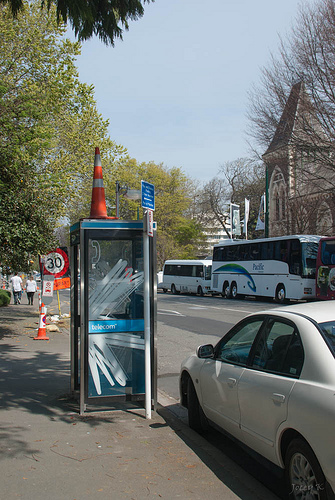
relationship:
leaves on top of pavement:
[8, 314, 30, 339] [5, 300, 69, 416]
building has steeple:
[243, 87, 334, 245] [277, 76, 335, 156]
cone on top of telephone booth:
[85, 142, 113, 235] [65, 226, 164, 404]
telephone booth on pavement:
[65, 226, 164, 404] [0, 300, 274, 500]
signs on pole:
[38, 247, 73, 295] [54, 292, 74, 330]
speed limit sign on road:
[42, 249, 58, 274] [55, 287, 193, 392]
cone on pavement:
[31, 301, 54, 344] [0, 300, 274, 500]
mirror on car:
[192, 339, 217, 366] [197, 320, 326, 446]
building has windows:
[243, 87, 334, 245] [259, 169, 292, 229]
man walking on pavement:
[9, 269, 22, 309] [0, 300, 274, 500]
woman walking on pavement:
[21, 266, 36, 306] [0, 300, 274, 500]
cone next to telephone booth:
[85, 142, 113, 235] [65, 226, 164, 404]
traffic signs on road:
[27, 236, 81, 337] [55, 287, 193, 392]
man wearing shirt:
[9, 269, 22, 309] [11, 276, 19, 292]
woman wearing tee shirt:
[21, 266, 36, 306] [24, 282, 35, 294]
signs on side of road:
[38, 247, 73, 295] [55, 287, 193, 392]